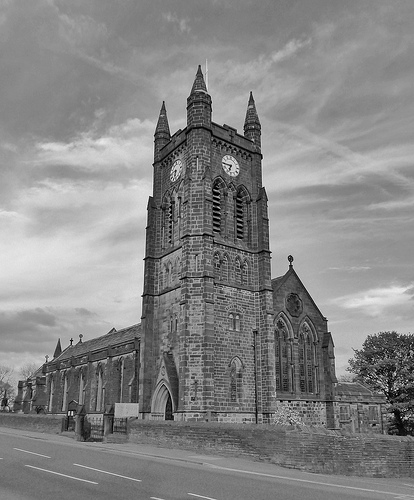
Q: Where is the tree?
A: Near building.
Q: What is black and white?
A: Photo.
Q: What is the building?
A: Church.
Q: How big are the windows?
A: Big.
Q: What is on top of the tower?
A: Spires.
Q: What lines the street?
A: Wall.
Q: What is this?
A: Church.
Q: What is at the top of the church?
A: Clock.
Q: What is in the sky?
A: Clouds.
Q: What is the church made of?
A: Bricks.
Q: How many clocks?
A: W.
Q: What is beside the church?
A: Tree.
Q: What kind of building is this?
A: Church.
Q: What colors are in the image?
A: Gray and white.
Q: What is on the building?
A: A clock.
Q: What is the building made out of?
A: Brick.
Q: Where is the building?
A: Next to the road.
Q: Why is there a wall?
A: To separate from the road.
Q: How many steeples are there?
A: 4.